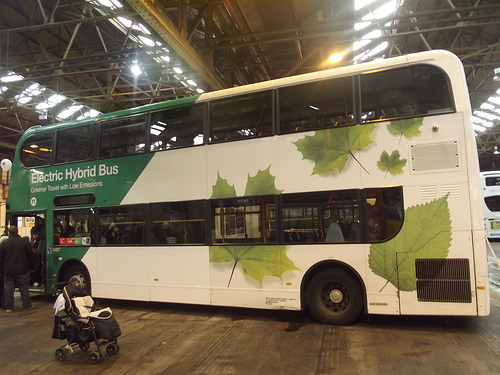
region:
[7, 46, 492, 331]
Double decker passenger bus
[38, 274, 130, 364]
Empty stroller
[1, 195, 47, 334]
Man talking to a bus driver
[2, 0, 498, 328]
Bus parker under a metal structure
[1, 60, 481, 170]
Row of bus windows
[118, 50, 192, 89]
Light hanging from the ceiling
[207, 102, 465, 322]
Decals of leaves on the side of the bus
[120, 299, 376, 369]
Concrete floor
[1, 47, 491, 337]
Electric Hybrid Bus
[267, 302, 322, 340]
Fluid leaking onto the concrete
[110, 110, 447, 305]
this is a bus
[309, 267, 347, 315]
this is the wheel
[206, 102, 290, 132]
this is a window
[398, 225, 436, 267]
this is a leaf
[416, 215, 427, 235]
the leaf is green in color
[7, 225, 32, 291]
this is a man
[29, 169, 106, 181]
this is a writing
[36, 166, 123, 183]
the writing is in white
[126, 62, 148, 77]
this is a light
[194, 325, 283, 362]
this is a road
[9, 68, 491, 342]
green and white double decker bus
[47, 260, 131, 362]
empty black stroller in front of bus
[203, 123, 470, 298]
large green leaves on side of bus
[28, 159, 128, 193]
white lettering on side of bus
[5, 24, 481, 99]
exposed rafters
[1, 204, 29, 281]
man wearing black jacket boarding bus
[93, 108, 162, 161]
slightly open window on second level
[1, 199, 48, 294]
open bus door with man standing in it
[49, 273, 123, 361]
stroller with bags on back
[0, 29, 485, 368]
large bus parked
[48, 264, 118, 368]
A stroller is visible.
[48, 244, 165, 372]
A stroller is visible.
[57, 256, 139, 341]
A stroller is visible.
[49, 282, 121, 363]
black and white baby stroller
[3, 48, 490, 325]
green and white bus with leaves on the side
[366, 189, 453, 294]
picture of a leaf on the side of the bus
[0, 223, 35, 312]
man standing outside the entry to the bus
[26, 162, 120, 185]
Electric Hybrid Bus written on the side of the bus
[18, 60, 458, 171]
row of seven windows on the upper deck of the bus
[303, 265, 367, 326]
back tire of the bus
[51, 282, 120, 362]
empty baby stroller in front of the bus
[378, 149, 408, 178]
picture of a small leaf on the rear side of the bus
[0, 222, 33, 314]
passenger waiting to board the bus